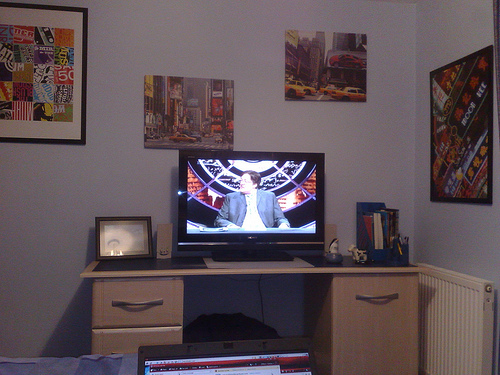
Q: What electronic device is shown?
A: TV.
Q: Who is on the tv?
A: A man.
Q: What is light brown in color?
A: Desk.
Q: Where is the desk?
A: Corner of the room.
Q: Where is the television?
A: On the desk.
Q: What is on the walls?
A: Art work.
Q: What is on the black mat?
A: Framed certificate.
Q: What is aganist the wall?
A: Ridged panel.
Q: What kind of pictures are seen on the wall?
A: Traffic pictures.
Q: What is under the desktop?
A: Drawers.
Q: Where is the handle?
A: In the drawer.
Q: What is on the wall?
A: A framed picture.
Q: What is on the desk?
A: A television.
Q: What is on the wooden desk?
A: A television.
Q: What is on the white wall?
A: Several pictures.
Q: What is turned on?
A: A television.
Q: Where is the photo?
A: On the wall.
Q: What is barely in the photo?
A: A laptop.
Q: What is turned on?
A: A television.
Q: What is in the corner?
A: A small wooden desk.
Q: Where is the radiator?
A: On the wall.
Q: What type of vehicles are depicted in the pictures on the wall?
A: Cars.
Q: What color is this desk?
A: Brown.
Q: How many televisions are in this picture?
A: One.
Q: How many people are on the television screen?
A: One.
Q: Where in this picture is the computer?
A: The bottom.